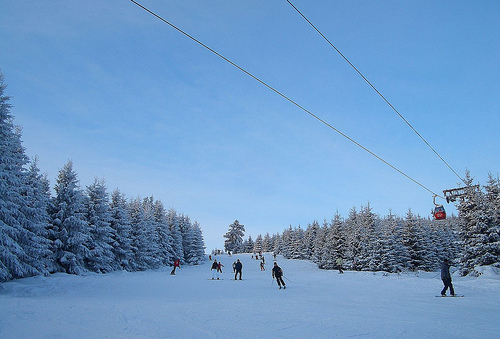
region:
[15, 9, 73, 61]
white clouds in blue sky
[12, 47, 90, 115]
white clouds in blue sky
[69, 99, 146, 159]
white clouds in blue sky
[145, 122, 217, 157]
white clouds in blue sky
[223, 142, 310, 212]
white clouds in blue sky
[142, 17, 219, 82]
white clouds in blue sky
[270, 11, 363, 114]
white clouds in blue sky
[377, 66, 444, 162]
white clouds in blue sky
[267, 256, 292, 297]
person skiing on hill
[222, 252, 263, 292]
person skiing on hill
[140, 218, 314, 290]
People on the slope.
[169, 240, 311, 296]
People skiing in the snow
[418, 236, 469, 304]
A man wearing skis.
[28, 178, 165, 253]
Snow on the trees.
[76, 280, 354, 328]
Snow on the ground.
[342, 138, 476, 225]
Skyline in the sky.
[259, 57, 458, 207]
Wires in the sky.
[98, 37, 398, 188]
The sky is blue.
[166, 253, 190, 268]
The person is wearing a red jacket.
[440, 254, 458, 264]
The man is wearing a cap.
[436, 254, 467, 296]
a person in the foreground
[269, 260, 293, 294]
a person on skis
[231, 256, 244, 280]
a person on skis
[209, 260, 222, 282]
a person on skis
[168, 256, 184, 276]
a person on skis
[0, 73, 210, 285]
a patch of trees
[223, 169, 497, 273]
a patch of trees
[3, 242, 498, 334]
a snow covered area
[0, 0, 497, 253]
a section of blue sky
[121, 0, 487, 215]
two ski lift cables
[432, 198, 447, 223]
Ski lift cable car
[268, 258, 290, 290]
Downhill skier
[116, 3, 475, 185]
Ski lift cables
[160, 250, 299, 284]
Many skiers going downhill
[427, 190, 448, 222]
Red ski lift cable car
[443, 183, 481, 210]
Cable car ski lift support pole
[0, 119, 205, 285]
Line of snow covered pine trees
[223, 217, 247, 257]
Snow covered pine tree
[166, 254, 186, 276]
A Skier in a red jacket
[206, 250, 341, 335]
Snow covered ski slope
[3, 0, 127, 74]
white clouds against blue sky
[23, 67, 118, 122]
white clouds against blue sky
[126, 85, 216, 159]
white clouds against blue sky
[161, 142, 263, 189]
white clouds against blue sky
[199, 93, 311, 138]
white clouds against blue sky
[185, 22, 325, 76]
white clouds against blue sky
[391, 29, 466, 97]
white clouds against blue sky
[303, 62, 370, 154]
white clouds against blue sky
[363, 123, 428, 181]
white clouds against blue sky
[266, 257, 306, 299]
skier